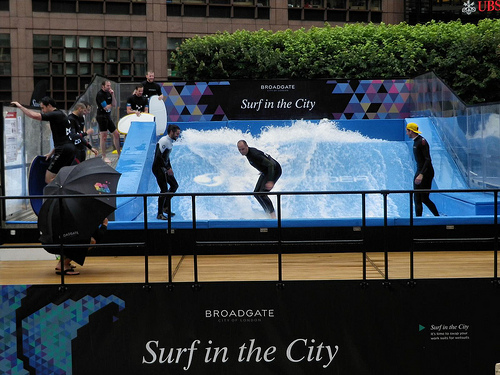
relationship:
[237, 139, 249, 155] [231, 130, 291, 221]
head of person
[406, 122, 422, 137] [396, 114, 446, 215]
head of person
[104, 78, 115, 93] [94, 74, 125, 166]
head of person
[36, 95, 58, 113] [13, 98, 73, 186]
head of person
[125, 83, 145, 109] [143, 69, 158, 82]
person of head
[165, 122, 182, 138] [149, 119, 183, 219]
head of person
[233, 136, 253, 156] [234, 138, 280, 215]
head of person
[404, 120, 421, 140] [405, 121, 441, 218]
head of person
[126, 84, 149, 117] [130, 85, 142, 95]
person has head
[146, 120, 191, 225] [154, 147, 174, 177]
person has arm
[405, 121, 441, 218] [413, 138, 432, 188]
person has arm